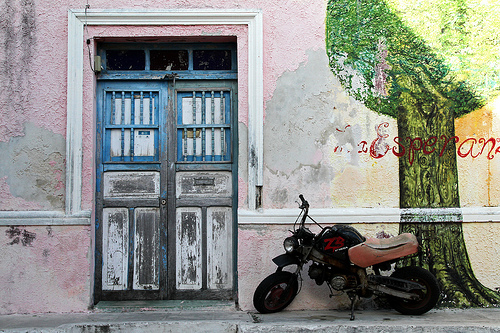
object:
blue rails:
[178, 91, 234, 163]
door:
[166, 80, 238, 300]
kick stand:
[349, 292, 356, 321]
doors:
[94, 34, 236, 309]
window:
[95, 42, 238, 80]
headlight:
[283, 236, 299, 254]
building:
[4, 12, 490, 253]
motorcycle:
[252, 194, 441, 321]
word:
[355, 118, 496, 160]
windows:
[72, 30, 270, 112]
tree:
[327, 1, 499, 308]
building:
[0, 2, 499, 329]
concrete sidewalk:
[0, 310, 499, 331]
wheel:
[385, 266, 440, 315]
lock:
[161, 199, 166, 205]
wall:
[8, 2, 73, 222]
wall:
[256, 34, 343, 170]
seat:
[348, 230, 419, 268]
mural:
[325, 0, 499, 308]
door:
[95, 80, 238, 302]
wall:
[237, 2, 498, 306]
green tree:
[323, 0, 498, 309]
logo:
[317, 225, 369, 262]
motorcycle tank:
[348, 231, 418, 268]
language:
[333, 122, 500, 163]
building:
[4, 3, 442, 332]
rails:
[91, 70, 238, 171]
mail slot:
[104, 171, 160, 198]